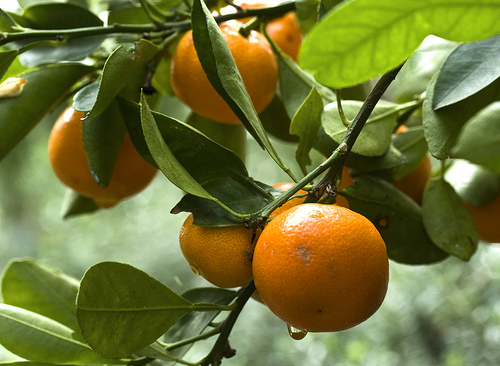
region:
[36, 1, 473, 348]
Orange fruit with tree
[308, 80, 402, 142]
Stem of the orange tree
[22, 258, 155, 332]
Leaves of the orange tree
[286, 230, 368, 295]
Orange color fruit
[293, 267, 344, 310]
Rind of the orange fruit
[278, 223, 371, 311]
Outer layer of the orange fruit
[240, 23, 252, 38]
Stem of the orange fruit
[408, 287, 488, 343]
Some plant near the orange tree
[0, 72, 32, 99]
Flower of the orange tree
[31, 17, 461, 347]
Lot of orange fruits in the tree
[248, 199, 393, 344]
Dew drop hanging precariously from an orange.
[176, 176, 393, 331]
Three ripe oranges ready for harvesting.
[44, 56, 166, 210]
A ripe orange sits behind green leaves.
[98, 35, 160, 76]
A partially eaten orange tree leaf.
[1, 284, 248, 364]
Green orange tree leaves on a branch.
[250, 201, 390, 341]
A solitary water drop hangs from a ripe orange.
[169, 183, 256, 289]
A partially eaten leaf sits atop a fresh orange.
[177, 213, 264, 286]
A fresh naval orange shows off it's belly button.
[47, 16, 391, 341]
A group of fresh oranges hang amongst green leaves.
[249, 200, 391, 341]
A glistening drop of water prepares to fall from a fresh orange.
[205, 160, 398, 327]
oranges attached to the branch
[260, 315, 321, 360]
a drop of water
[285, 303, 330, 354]
a drop of water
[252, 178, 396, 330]
Orange hanging from a tree.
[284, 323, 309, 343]
Drop of water on an orange.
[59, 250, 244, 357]
Leave connected to a branch.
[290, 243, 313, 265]
Bruise on an orange.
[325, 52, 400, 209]
A long stem of a tree.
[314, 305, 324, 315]
Black spot on an orange.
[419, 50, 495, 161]
Bunch of leaves on a tree.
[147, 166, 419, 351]
Bunch of oranges on a branch.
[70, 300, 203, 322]
Stem of a leave.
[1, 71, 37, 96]
Yellow spot on a leaf.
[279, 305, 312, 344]
water drop on the orange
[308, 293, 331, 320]
brown spot on the orange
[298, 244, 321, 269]
white spot on the orange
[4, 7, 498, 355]
oranges hanging on tree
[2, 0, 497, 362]
leaves around the oranges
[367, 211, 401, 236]
brown spot on leaf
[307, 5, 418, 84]
lines on the leaf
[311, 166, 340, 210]
branch attached to orange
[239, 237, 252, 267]
brown spot on the orange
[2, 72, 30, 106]
orange piece on the leaf